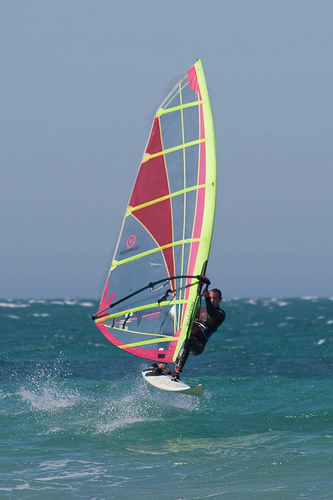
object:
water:
[0, 296, 333, 500]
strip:
[141, 138, 207, 165]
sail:
[91, 55, 216, 371]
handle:
[197, 275, 211, 298]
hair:
[210, 288, 222, 298]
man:
[148, 288, 226, 380]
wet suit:
[161, 295, 226, 374]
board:
[141, 367, 203, 398]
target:
[125, 235, 136, 249]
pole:
[146, 367, 163, 376]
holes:
[152, 363, 159, 370]